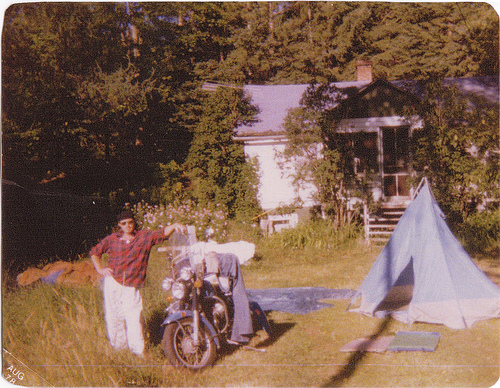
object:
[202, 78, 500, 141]
roof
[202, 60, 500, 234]
building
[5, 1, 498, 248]
forest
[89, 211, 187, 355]
man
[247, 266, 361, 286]
tarp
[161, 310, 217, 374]
wheel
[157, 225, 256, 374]
bike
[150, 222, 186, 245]
hand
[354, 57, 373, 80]
chimney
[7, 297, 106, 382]
grass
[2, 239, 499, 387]
ground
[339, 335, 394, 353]
mat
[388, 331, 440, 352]
mat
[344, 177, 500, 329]
tent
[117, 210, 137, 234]
head